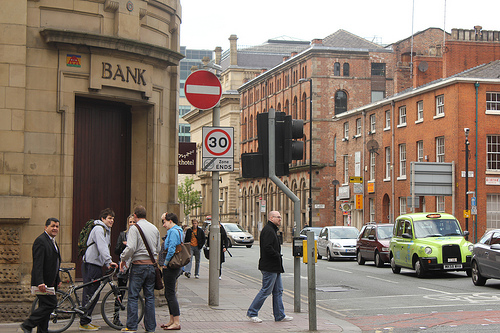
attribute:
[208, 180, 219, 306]
pole — thick, metal, sign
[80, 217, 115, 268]
hoodie — grey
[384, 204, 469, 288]
cab — lime green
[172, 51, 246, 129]
sign — red, round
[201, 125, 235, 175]
sign — white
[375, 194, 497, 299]
car — yellow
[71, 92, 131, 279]
door — brown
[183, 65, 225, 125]
sign — white, red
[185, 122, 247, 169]
writing — black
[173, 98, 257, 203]
sign — white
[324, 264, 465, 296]
lines — white, dashed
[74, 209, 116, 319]
man — young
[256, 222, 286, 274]
jacket — black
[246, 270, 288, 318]
pants — blue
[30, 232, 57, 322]
suit — black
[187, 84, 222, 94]
bar — white